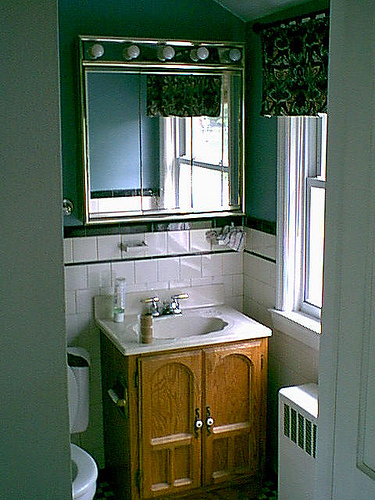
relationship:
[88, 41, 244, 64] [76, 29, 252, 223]
bulbs are above cabinet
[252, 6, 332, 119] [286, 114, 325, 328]
curtain over window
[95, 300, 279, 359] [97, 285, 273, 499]
sink in bathroom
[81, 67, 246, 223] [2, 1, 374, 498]
mirror in bathroom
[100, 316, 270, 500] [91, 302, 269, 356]
cabinet under sink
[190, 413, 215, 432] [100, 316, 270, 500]
knobs are on cabinet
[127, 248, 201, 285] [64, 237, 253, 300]
tile on wall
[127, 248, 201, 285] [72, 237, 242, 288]
tile on wall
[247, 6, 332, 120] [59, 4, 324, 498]
curtain in bathroom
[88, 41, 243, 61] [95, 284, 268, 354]
bulbs above sink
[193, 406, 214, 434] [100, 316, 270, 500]
knobs on cabinet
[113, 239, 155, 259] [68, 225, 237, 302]
dish mounted on wall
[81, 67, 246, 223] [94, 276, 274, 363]
mirror above sink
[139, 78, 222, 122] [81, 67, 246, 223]
reflection in mirror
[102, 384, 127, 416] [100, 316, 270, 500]
holder attached to cabinet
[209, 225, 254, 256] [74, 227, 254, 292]
hand towel on wall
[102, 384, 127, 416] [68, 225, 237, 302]
holder on wall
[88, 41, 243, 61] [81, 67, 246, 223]
bulbs on a mirror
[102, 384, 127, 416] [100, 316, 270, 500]
holder on a cabinet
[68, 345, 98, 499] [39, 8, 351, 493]
toilet in bathroom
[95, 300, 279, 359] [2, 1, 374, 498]
sink in bathroom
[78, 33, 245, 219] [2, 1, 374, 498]
medicine cabinet in bathroom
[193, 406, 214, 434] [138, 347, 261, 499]
knobs on doors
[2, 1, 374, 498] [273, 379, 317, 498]
bathroom has heater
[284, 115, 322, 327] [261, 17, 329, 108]
bathroom window with curtain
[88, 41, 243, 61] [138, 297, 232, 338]
bulbs over bathroom sink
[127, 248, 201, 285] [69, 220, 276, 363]
tile on bathroom wall